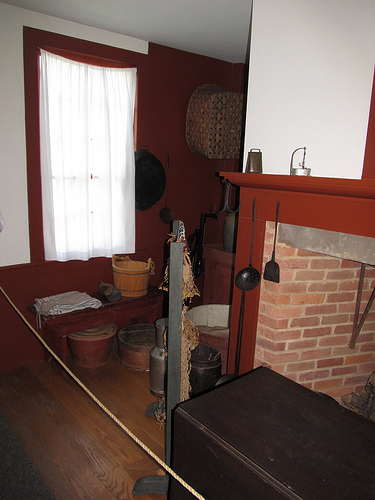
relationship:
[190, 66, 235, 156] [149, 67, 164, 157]
wicker attached to wall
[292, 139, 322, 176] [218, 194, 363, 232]
cow bell on top of mantle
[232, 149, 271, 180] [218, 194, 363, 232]
oil canter on top of mantle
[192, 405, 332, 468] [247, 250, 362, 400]
hope chest next to fireplace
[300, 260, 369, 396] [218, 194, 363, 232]
fire scoop hanging from mantle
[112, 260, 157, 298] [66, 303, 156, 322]
pail on top of bench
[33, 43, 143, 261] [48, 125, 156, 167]
curtains hanging from window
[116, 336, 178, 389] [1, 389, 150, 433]
churn on top of floor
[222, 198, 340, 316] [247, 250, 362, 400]
utensisl hanging on fireplace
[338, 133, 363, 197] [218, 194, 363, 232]
grater on top of mantle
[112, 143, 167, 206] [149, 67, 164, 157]
pan hanging on wall